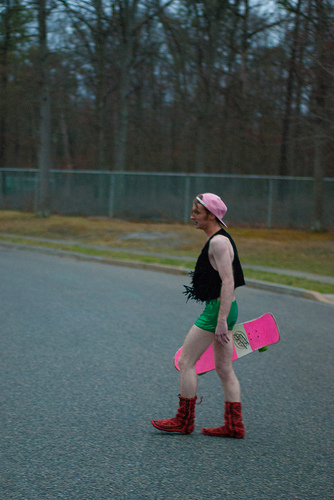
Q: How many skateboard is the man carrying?
A: 1.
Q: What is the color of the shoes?
A: Red.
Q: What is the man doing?
A: Walking.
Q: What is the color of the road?
A: Grey.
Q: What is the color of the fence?
A: Blue.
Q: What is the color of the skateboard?
A: Pink.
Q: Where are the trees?
A: Behind the fence.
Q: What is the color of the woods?
A: Brown.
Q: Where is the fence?
A: In front of the trees.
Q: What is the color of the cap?
A: Pink.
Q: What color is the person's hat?
A: Pink.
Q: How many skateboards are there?
A: One.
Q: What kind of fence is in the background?
A: Metal.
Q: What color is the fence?
A: Grey.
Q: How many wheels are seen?
A: One.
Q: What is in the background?
A: Trees.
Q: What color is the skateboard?
A: Pink.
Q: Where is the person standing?
A: On the street.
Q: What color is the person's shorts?
A: Green.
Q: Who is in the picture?
A: A man.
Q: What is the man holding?
A: A skateboard.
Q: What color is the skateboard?
A: Pink.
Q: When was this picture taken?
A: Daytime.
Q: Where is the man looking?
A: Left.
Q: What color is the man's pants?
A: Green.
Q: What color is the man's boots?
A: Red.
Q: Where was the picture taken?
A: In the street.